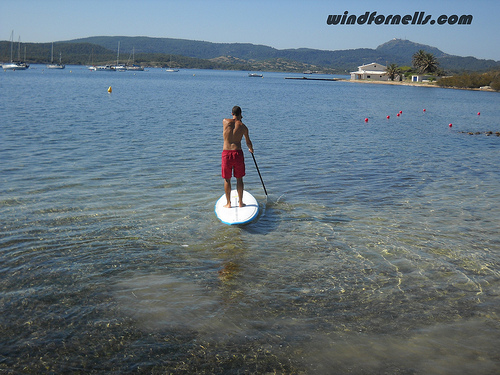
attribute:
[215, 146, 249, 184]
shorts — red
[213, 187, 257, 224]
paddle board — white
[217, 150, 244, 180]
swim trunks —  red , for swim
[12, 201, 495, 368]
sea grass —  in sea 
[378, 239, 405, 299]
wave — tiny, white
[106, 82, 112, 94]
buoy —  yellow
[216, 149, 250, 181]
trunks — red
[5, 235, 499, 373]
shallow water —  Shallow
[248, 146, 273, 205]
paddle — black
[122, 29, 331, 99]
hills —  in horizon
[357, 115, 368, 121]
buoy — red, lobster traps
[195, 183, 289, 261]
board — paddle, white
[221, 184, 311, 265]
board —  White, for paddle,  edged in blue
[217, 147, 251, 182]
swimming trunks — red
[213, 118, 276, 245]
board — blue, white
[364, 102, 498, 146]
buoys — small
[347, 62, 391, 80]
building — white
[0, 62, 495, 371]
water —  shallow, shallow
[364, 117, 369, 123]
ball — red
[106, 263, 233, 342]
puddle — small 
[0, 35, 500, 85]
terrain — hilly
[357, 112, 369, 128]
buoy —  Red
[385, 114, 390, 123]
buoy —  Red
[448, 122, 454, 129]
buoy —  Red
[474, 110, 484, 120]
buoy —  Red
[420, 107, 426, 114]
buoy —  Red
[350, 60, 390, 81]
house — white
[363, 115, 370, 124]
ball — red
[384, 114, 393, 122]
ball — red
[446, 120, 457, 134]
ball — red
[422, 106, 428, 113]
ball — red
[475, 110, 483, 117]
ball — red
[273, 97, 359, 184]
waters — blue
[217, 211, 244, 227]
stripe — blue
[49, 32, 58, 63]
sails —  down